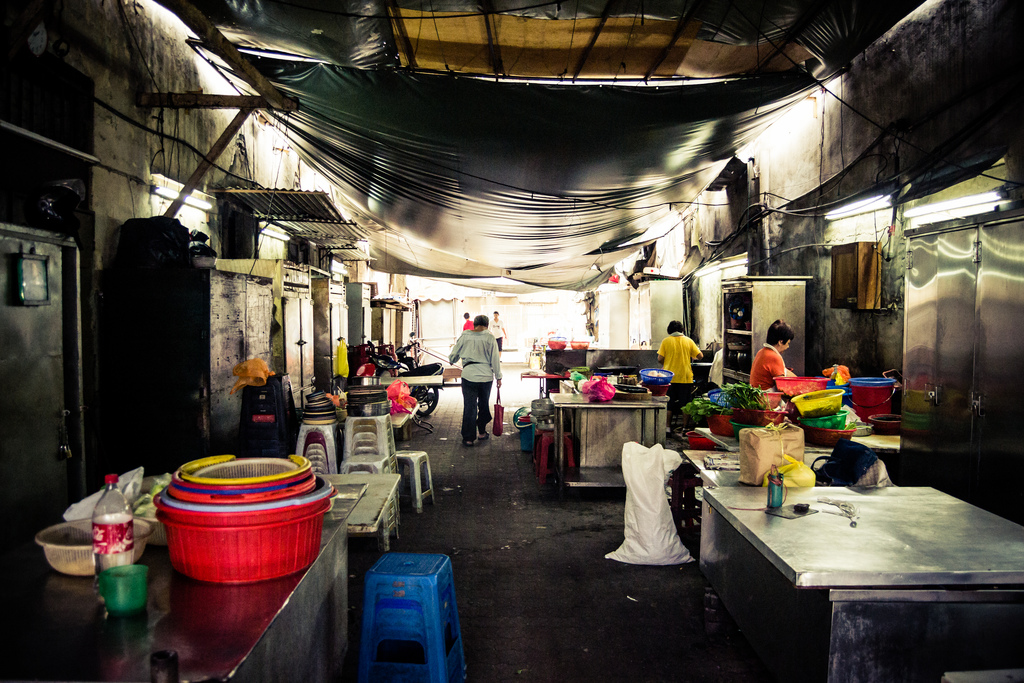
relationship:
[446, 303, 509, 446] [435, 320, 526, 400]
person wearing shirt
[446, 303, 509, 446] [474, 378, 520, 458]
person holding bag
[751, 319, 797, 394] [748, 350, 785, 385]
woman has shirt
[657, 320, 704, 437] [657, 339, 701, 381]
person has shirt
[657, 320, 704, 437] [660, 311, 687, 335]
person has hair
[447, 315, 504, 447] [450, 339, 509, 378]
person has shirt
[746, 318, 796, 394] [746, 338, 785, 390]
woman wearing shirt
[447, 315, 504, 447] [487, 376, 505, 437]
person carrying bag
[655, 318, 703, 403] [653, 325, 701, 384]
person wearing shirt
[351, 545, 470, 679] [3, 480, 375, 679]
stool standing next to table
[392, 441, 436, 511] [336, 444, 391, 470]
stool standing next to stool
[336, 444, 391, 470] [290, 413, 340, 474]
stool standing next to stool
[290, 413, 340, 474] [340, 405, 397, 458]
stool standing next to stool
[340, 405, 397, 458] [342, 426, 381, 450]
stool stacked onto stool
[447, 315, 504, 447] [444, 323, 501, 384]
person wearing shirt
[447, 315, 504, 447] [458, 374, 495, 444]
person wearing jeans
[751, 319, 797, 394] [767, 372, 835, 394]
woman standing next to bowl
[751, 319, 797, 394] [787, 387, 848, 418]
woman standing next to bowl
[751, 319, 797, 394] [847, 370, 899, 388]
woman standing next to bowl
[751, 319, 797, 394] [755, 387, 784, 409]
woman standing next to bowl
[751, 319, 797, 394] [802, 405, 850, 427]
woman standing next to bowl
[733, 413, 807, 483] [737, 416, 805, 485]
package wrapped in package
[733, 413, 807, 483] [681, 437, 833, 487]
package sitting on top of table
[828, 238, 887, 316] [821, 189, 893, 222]
cabinet hanging underneath light